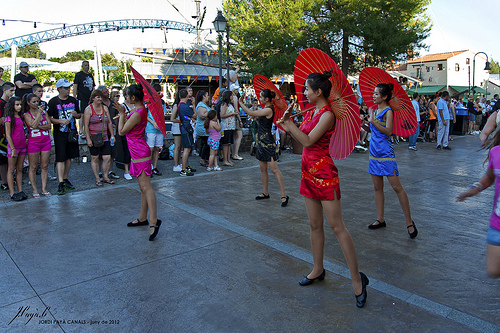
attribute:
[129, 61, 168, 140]
umbrella — red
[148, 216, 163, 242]
shoe — black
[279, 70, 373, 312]
woman — dancing, waving, moving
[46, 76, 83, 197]
man — watching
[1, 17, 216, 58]
arch — behind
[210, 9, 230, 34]
light — off, green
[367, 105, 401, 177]
skirt — blue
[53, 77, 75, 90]
cap — white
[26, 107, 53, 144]
tank — pink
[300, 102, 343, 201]
dress — red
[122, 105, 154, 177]
outfit — pink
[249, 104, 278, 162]
flapper — black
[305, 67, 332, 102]
hair — black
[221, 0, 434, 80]
tree — green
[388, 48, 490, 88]
building — behind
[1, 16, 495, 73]
wire — behind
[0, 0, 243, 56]
sky — cloudy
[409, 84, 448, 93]
awning — green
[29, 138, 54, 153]
shorts — pink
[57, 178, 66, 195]
sneaker — black